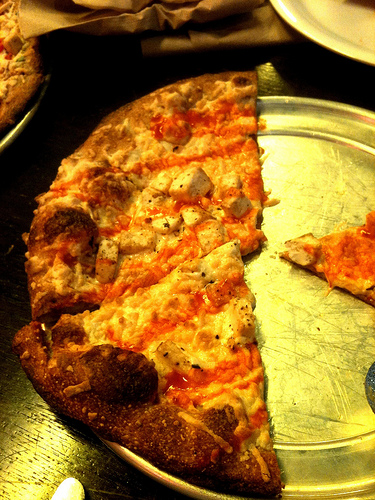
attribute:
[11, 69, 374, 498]
pizza — partially eaten, chicken pizza, incomplete, sliced, cut up, half eaten, silver, chicken, cheese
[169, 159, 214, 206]
chicken — white meat, diced, white, cubed, large cube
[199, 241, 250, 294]
chicken — white meat, diced, white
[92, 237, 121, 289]
chicken — white meat, diced, white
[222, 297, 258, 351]
chicken — white meat, diced, white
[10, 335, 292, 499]
crust — crispy, brown, burnt, black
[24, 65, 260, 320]
crust — crispy, brown, burnt, black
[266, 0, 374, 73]
pizza pan — silver, shiny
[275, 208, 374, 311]
slice — singular, pizza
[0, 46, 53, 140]
edge — crispy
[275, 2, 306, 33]
reflection — light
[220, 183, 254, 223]
chicken — diced, white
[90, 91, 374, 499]
pizza tray — scarred, metal, scratched, silver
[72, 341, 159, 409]
air bubble — burned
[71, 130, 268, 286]
cheese — white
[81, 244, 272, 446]
cheese — white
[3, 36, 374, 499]
table — wooden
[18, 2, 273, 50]
napkin — crumpled, brown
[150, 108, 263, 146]
sauce — red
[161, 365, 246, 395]
sauce — red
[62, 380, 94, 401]
cheese — hardened